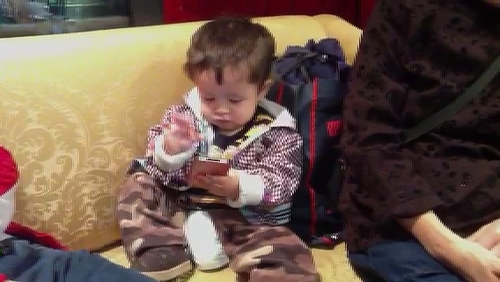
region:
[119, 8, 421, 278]
a boy sitting on a couch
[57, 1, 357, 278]
a child sitting on the couch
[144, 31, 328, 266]
a boy wearing a jacket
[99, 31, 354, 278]
a child wearing a jacket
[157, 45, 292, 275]
a child holding a phone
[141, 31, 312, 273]
a child holding a cell phone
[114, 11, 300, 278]
a child looking at a phone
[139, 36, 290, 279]
a child lookign at a cell phone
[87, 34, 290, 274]
a child wearing pants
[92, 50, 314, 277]
a child wearing shoes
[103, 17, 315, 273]
the baby is sitting on the couch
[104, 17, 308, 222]
the boy is holding a phone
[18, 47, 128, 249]
the couch is paisley print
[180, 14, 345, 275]
the child is leaning on a bag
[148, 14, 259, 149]
the child is looking down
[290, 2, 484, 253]
an adult sitting next to the child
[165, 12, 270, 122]
the child`s hair is dark brown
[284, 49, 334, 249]
the bag has a line on it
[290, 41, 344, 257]
the line on the bag is red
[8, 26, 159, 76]
the light is on the couch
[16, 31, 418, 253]
this is a child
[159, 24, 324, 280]
the child is holding a phone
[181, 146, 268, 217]
this is a smart phone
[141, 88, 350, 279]
the child is wearing a jacket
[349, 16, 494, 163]
this person is wearing brown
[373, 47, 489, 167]
the person has a strap from a bag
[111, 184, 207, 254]
the childs pants are camo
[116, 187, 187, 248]
the camo is brown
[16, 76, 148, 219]
the couch is yellow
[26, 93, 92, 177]
the couch is floral pattern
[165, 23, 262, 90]
child has brown hair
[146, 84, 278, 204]
child has brown coat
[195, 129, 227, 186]
child is holding cell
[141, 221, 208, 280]
child has black shoes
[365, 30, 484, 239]
person has brown shirt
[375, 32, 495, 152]
black strap on shirt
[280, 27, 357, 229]
blue and red bag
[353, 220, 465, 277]
person has blue pants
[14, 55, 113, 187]
yellow sofa behind people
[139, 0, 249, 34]
red wall behind child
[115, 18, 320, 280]
kid is sitting down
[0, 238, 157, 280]
the fabric is blue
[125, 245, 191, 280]
kid's shoe is brown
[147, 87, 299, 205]
kis is wearing jacket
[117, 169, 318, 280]
the pants are camouflage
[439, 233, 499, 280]
hand of a woman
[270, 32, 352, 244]
blue and red backpack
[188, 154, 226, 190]
the phone is pink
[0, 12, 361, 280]
the couch is yellow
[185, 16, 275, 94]
the hair is brown